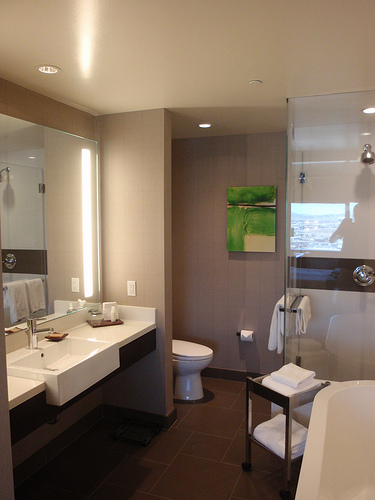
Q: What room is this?
A: Bathroom.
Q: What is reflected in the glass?
A: A person.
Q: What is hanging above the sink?
A: A mirror.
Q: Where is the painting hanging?
A: On a wall.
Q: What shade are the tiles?
A: Brown.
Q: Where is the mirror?
A: Wall.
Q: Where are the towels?
A: Rack.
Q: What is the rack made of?
A: Wood.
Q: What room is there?
A: Bathroom.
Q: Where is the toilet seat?
A: Corner.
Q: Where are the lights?
A: Ceiling.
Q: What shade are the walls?
A: Light brown.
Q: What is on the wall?
A: Mirror.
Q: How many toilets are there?
A: One.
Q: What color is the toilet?
A: White.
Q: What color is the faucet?
A: Silver.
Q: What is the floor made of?
A: Tile.